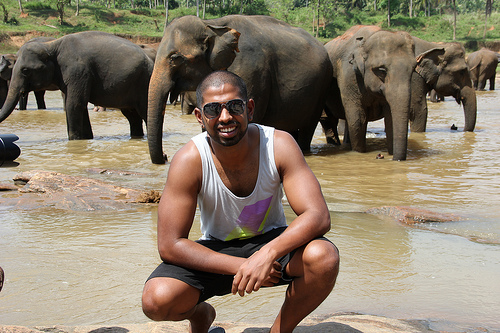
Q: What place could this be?
A: It is a lake.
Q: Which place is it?
A: It is a lake.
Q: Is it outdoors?
A: Yes, it is outdoors.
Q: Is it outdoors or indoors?
A: It is outdoors.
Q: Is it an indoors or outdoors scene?
A: It is outdoors.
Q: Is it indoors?
A: No, it is outdoors.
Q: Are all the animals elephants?
A: Yes, all the animals are elephants.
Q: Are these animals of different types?
A: No, all the animals are elephants.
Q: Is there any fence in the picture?
A: No, there are no fences.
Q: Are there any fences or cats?
A: No, there are no fences or cats.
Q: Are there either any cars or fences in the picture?
A: No, there are no cars or fences.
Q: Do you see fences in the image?
A: No, there are no fences.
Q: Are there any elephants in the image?
A: Yes, there is an elephant.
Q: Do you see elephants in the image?
A: Yes, there is an elephant.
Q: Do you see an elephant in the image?
A: Yes, there is an elephant.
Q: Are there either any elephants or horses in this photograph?
A: Yes, there is an elephant.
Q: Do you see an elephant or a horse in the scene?
A: Yes, there is an elephant.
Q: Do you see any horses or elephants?
A: Yes, there is an elephant.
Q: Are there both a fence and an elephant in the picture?
A: No, there is an elephant but no fences.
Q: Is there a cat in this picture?
A: No, there are no cats.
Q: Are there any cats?
A: No, there are no cats.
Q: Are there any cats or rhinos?
A: No, there are no cats or rhinos.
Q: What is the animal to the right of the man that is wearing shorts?
A: The animal is an elephant.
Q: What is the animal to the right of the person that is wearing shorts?
A: The animal is an elephant.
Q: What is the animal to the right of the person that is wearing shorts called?
A: The animal is an elephant.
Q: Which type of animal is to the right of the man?
A: The animal is an elephant.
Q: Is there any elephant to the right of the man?
A: Yes, there is an elephant to the right of the man.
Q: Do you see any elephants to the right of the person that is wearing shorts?
A: Yes, there is an elephant to the right of the man.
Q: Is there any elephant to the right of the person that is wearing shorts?
A: Yes, there is an elephant to the right of the man.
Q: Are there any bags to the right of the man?
A: No, there is an elephant to the right of the man.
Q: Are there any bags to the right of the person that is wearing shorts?
A: No, there is an elephant to the right of the man.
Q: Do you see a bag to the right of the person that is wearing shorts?
A: No, there is an elephant to the right of the man.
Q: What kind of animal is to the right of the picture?
A: The animal is an elephant.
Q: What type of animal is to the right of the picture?
A: The animal is an elephant.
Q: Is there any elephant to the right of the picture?
A: Yes, there is an elephant to the right of the picture.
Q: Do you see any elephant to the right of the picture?
A: Yes, there is an elephant to the right of the picture.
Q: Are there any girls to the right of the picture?
A: No, there is an elephant to the right of the picture.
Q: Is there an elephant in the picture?
A: Yes, there is an elephant.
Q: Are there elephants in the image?
A: Yes, there is an elephant.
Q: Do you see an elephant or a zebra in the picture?
A: Yes, there is an elephant.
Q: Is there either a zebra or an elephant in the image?
A: Yes, there is an elephant.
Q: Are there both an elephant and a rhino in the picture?
A: No, there is an elephant but no rhinos.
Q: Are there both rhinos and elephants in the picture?
A: No, there is an elephant but no rhinos.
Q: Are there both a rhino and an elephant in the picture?
A: No, there is an elephant but no rhinos.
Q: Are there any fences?
A: No, there are no fences.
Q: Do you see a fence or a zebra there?
A: No, there are no fences or zebras.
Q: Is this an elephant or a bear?
A: This is an elephant.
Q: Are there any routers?
A: No, there are no routers.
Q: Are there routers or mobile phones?
A: No, there are no routers or mobile phones.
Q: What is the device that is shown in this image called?
A: The device is a monitor.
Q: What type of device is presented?
A: The device is a monitor.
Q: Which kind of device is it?
A: The device is a monitor.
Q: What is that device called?
A: This is a monitor.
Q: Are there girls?
A: No, there are no girls.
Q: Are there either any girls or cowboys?
A: No, there are no girls or cowboys.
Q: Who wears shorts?
A: The man wears shorts.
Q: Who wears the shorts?
A: The man wears shorts.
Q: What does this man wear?
A: The man wears shorts.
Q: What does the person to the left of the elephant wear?
A: The man wears shorts.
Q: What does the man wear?
A: The man wears shorts.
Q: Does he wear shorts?
A: Yes, the man wears shorts.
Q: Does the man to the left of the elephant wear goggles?
A: No, the man wears shorts.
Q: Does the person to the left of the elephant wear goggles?
A: No, the man wears shorts.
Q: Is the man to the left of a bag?
A: No, the man is to the left of an elephant.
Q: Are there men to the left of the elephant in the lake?
A: Yes, there is a man to the left of the elephant.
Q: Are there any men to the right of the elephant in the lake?
A: No, the man is to the left of the elephant.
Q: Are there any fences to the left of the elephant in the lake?
A: No, there is a man to the left of the elephant.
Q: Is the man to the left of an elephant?
A: Yes, the man is to the left of an elephant.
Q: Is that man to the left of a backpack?
A: No, the man is to the left of an elephant.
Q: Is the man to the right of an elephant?
A: No, the man is to the left of an elephant.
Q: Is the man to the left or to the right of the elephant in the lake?
A: The man is to the left of the elephant.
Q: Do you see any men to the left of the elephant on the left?
A: No, the man is to the right of the elephant.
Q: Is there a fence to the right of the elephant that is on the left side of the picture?
A: No, there is a man to the right of the elephant.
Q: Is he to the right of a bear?
A: No, the man is to the right of an elephant.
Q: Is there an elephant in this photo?
A: Yes, there is an elephant.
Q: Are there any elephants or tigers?
A: Yes, there is an elephant.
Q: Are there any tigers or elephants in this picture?
A: Yes, there is an elephant.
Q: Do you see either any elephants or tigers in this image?
A: Yes, there is an elephant.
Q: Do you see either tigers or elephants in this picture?
A: Yes, there is an elephant.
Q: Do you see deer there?
A: No, there are no deer.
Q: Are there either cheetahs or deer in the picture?
A: No, there are no deer or cheetahs.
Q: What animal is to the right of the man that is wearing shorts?
A: The animal is an elephant.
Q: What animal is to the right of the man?
A: The animal is an elephant.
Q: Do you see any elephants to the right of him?
A: Yes, there is an elephant to the right of the man.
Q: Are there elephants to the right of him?
A: Yes, there is an elephant to the right of the man.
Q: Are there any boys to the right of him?
A: No, there is an elephant to the right of the man.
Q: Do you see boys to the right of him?
A: No, there is an elephant to the right of the man.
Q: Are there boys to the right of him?
A: No, there is an elephant to the right of the man.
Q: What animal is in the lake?
A: The animal is an elephant.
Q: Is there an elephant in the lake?
A: Yes, there is an elephant in the lake.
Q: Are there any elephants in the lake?
A: Yes, there is an elephant in the lake.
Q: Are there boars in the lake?
A: No, there is an elephant in the lake.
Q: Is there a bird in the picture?
A: No, there are no birds.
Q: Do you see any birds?
A: No, there are no birds.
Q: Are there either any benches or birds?
A: No, there are no birds or benches.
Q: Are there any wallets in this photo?
A: No, there are no wallets.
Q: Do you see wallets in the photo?
A: No, there are no wallets.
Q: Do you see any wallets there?
A: No, there are no wallets.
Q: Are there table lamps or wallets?
A: No, there are no wallets or table lamps.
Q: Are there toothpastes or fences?
A: No, there are no fences or toothpastes.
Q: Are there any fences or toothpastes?
A: No, there are no fences or toothpastes.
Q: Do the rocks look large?
A: Yes, the rocks are large.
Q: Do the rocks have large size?
A: Yes, the rocks are large.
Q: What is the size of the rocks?
A: The rocks are large.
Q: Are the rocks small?
A: No, the rocks are large.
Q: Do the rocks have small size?
A: No, the rocks are large.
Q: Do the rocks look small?
A: No, the rocks are large.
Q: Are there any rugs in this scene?
A: No, there are no rugs.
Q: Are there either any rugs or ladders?
A: No, there are no rugs or ladders.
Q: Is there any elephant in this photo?
A: Yes, there is an elephant.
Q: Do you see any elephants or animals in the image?
A: Yes, there is an elephant.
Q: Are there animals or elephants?
A: Yes, there is an elephant.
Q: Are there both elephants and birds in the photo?
A: No, there is an elephant but no birds.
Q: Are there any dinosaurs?
A: No, there are no dinosaurs.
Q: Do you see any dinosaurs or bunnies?
A: No, there are no dinosaurs or bunnies.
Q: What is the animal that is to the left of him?
A: The animal is an elephant.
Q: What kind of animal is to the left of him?
A: The animal is an elephant.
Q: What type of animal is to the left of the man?
A: The animal is an elephant.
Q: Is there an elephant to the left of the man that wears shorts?
A: Yes, there is an elephant to the left of the man.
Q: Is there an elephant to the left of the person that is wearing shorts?
A: Yes, there is an elephant to the left of the man.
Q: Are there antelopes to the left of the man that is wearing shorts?
A: No, there is an elephant to the left of the man.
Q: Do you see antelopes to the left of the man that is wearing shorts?
A: No, there is an elephant to the left of the man.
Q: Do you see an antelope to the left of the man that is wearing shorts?
A: No, there is an elephant to the left of the man.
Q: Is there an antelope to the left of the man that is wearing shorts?
A: No, there is an elephant to the left of the man.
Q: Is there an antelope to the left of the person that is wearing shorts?
A: No, there is an elephant to the left of the man.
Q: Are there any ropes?
A: No, there are no ropes.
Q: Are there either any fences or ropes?
A: No, there are no ropes or fences.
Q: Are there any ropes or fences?
A: No, there are no ropes or fences.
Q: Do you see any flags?
A: No, there are no flags.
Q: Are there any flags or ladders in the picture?
A: No, there are no flags or ladders.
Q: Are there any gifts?
A: No, there are no gifts.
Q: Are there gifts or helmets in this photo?
A: No, there are no gifts or helmets.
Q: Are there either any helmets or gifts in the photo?
A: No, there are no gifts or helmets.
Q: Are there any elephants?
A: Yes, there is an elephant.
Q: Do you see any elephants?
A: Yes, there is an elephant.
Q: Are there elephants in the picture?
A: Yes, there is an elephant.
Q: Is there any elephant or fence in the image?
A: Yes, there is an elephant.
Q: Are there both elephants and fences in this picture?
A: No, there is an elephant but no fences.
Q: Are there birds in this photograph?
A: No, there are no birds.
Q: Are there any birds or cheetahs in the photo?
A: No, there are no birds or cheetahs.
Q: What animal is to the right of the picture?
A: The animal is an elephant.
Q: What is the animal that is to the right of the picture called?
A: The animal is an elephant.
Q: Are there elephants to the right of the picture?
A: Yes, there is an elephant to the right of the picture.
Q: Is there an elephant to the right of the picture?
A: Yes, there is an elephant to the right of the picture.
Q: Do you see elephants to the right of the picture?
A: Yes, there is an elephant to the right of the picture.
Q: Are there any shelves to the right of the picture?
A: No, there is an elephant to the right of the picture.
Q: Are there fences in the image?
A: No, there are no fences.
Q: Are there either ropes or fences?
A: No, there are no fences or ropes.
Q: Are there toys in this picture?
A: No, there are no toys.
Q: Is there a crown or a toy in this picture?
A: No, there are no toys or crowns.